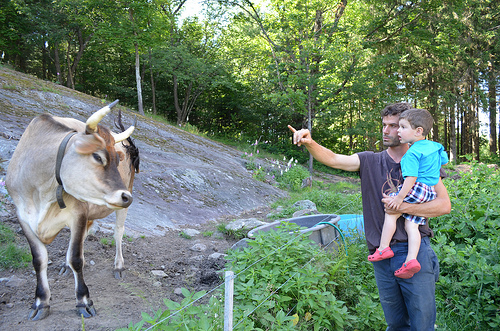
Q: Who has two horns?
A: The cow.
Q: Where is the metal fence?
A: Between the cow and the people.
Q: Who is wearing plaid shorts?
A: The boy in the blue shirt.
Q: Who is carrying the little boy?
A: The man in the jeans.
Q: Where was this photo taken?
A: At a zoo.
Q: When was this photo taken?
A: During the daytime.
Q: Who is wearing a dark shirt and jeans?
A: The man holding the boy.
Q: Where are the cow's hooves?
A: On the dirt.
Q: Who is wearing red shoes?
A: The little boy.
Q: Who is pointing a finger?
A: The man in jeans.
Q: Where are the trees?
A: In the background behind the people and the cow.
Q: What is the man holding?
A: Little boy.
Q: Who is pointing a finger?
A: The man.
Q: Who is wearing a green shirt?
A: Little boy.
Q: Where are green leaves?
A: On trees.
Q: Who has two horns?
A: Cow.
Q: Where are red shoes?
A: On boy's feet.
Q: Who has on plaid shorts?
A: Young boy.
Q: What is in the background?
A: Trees.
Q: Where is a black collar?
A: Around cow's neck.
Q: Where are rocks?
A: On the ground.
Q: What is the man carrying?
A: A child.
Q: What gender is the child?
A: A boy.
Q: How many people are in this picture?
A: 2.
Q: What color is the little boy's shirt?
A: Blue.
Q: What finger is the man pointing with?
A: Pinky finger.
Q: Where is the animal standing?
A: On the hill.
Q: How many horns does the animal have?
A: 2.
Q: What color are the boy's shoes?
A: Red.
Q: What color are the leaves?
A: Green.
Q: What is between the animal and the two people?
A: A fence.